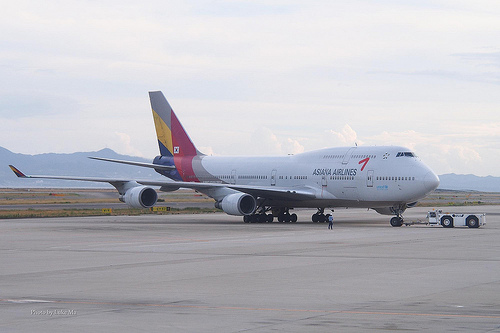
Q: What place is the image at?
A: It is at the runway.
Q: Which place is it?
A: It is a runway.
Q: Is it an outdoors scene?
A: Yes, it is outdoors.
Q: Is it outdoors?
A: Yes, it is outdoors.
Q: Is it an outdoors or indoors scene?
A: It is outdoors.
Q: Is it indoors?
A: No, it is outdoors.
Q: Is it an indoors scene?
A: No, it is outdoors.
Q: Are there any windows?
A: Yes, there are windows.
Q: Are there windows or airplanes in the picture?
A: Yes, there are windows.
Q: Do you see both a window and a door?
A: Yes, there are both a window and a door.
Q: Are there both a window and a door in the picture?
A: Yes, there are both a window and a door.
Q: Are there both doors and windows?
A: Yes, there are both windows and a door.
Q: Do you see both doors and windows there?
A: Yes, there are both windows and a door.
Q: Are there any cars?
A: No, there are no cars.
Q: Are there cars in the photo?
A: No, there are no cars.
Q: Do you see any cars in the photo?
A: No, there are no cars.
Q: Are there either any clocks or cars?
A: No, there are no cars or clocks.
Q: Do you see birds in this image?
A: No, there are no birds.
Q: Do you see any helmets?
A: No, there are no helmets.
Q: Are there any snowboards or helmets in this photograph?
A: No, there are no helmets or snowboards.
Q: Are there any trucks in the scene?
A: Yes, there is a truck.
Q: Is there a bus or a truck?
A: Yes, there is a truck.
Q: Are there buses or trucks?
A: Yes, there is a truck.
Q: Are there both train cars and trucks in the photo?
A: No, there is a truck but no train cars.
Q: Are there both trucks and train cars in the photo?
A: No, there is a truck but no train cars.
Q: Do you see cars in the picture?
A: No, there are no cars.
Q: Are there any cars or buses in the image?
A: No, there are no cars or buses.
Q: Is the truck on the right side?
A: Yes, the truck is on the right of the image.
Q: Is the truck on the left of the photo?
A: No, the truck is on the right of the image.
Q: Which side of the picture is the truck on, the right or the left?
A: The truck is on the right of the image.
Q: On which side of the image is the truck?
A: The truck is on the right of the image.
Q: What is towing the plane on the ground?
A: The truck is towing the airplane.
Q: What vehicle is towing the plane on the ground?
A: The vehicle is a truck.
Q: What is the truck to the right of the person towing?
A: The truck is towing the plane.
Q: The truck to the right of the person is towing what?
A: The truck is towing the plane.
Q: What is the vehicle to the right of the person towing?
A: The truck is towing the plane.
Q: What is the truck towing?
A: The truck is towing the plane.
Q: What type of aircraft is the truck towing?
A: The truck is towing the plane.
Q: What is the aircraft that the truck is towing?
A: The aircraft is an airplane.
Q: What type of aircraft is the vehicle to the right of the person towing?
A: The truck is towing the plane.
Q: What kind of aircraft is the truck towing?
A: The truck is towing the plane.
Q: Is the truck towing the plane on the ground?
A: Yes, the truck is towing the plane.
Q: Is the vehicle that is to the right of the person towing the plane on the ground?
A: Yes, the truck is towing the plane.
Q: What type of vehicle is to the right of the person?
A: The vehicle is a truck.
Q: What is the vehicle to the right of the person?
A: The vehicle is a truck.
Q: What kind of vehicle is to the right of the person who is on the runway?
A: The vehicle is a truck.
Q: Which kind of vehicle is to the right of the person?
A: The vehicle is a truck.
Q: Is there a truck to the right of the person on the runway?
A: Yes, there is a truck to the right of the person.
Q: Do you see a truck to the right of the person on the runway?
A: Yes, there is a truck to the right of the person.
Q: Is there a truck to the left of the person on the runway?
A: No, the truck is to the right of the person.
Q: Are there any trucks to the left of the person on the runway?
A: No, the truck is to the right of the person.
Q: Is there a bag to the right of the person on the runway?
A: No, there is a truck to the right of the person.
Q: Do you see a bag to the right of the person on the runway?
A: No, there is a truck to the right of the person.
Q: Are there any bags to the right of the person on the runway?
A: No, there is a truck to the right of the person.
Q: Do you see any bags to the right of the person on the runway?
A: No, there is a truck to the right of the person.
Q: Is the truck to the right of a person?
A: Yes, the truck is to the right of a person.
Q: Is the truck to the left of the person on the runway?
A: No, the truck is to the right of the person.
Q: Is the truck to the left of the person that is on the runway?
A: No, the truck is to the right of the person.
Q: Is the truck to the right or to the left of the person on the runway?
A: The truck is to the right of the person.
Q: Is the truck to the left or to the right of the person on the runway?
A: The truck is to the right of the person.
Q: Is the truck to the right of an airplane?
A: Yes, the truck is to the right of an airplane.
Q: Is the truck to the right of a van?
A: No, the truck is to the right of an airplane.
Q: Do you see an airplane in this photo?
A: Yes, there is an airplane.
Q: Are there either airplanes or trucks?
A: Yes, there is an airplane.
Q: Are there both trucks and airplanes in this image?
A: Yes, there are both an airplane and a truck.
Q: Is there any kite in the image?
A: No, there are no kites.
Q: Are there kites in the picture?
A: No, there are no kites.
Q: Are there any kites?
A: No, there are no kites.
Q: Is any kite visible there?
A: No, there are no kites.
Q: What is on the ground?
A: The plane is on the ground.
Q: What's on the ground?
A: The plane is on the ground.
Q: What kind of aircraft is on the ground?
A: The aircraft is an airplane.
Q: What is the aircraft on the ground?
A: The aircraft is an airplane.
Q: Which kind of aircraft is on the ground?
A: The aircraft is an airplane.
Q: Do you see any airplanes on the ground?
A: Yes, there is an airplane on the ground.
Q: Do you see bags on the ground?
A: No, there is an airplane on the ground.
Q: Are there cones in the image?
A: No, there are no cones.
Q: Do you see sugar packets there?
A: No, there are no sugar packets.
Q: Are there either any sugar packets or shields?
A: No, there are no sugar packets or shields.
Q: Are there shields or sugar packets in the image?
A: No, there are no sugar packets or shields.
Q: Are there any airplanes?
A: Yes, there is an airplane.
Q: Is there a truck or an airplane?
A: Yes, there is an airplane.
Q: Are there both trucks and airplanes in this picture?
A: Yes, there are both an airplane and a truck.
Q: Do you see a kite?
A: No, there are no kites.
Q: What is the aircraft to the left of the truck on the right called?
A: The aircraft is an airplane.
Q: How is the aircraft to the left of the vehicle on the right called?
A: The aircraft is an airplane.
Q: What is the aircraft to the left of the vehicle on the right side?
A: The aircraft is an airplane.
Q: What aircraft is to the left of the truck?
A: The aircraft is an airplane.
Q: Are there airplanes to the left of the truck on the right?
A: Yes, there is an airplane to the left of the truck.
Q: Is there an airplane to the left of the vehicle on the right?
A: Yes, there is an airplane to the left of the truck.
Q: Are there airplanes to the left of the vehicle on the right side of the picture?
A: Yes, there is an airplane to the left of the truck.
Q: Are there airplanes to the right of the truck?
A: No, the airplane is to the left of the truck.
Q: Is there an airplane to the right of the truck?
A: No, the airplane is to the left of the truck.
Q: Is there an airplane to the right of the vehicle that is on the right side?
A: No, the airplane is to the left of the truck.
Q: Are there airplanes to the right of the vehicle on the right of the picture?
A: No, the airplane is to the left of the truck.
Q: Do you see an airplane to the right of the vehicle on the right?
A: No, the airplane is to the left of the truck.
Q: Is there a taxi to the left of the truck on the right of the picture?
A: No, there is an airplane to the left of the truck.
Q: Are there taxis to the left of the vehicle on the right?
A: No, there is an airplane to the left of the truck.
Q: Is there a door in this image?
A: Yes, there is a door.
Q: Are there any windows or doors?
A: Yes, there is a door.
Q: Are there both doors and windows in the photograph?
A: Yes, there are both a door and a window.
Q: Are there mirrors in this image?
A: No, there are no mirrors.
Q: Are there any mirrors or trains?
A: No, there are no mirrors or trains.